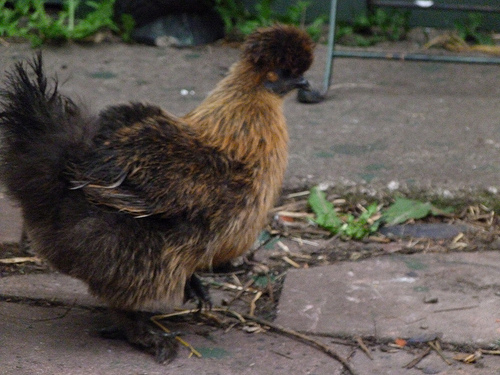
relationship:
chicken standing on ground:
[2, 23, 314, 333] [1, 35, 498, 374]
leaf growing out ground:
[309, 187, 381, 242] [1, 35, 498, 374]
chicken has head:
[2, 23, 314, 333] [239, 28, 311, 98]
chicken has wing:
[2, 23, 314, 333] [78, 117, 238, 218]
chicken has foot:
[2, 23, 314, 333] [102, 302, 180, 361]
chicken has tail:
[2, 23, 314, 333] [1, 53, 87, 237]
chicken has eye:
[2, 23, 314, 333] [280, 69, 291, 80]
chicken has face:
[2, 23, 314, 333] [275, 63, 309, 95]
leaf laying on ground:
[309, 187, 381, 242] [1, 35, 498, 374]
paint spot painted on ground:
[184, 341, 236, 359] [1, 35, 498, 374]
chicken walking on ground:
[2, 23, 314, 333] [1, 35, 498, 374]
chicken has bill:
[2, 23, 314, 333] [292, 78, 309, 90]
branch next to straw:
[233, 307, 353, 370] [153, 300, 254, 354]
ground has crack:
[1, 35, 498, 374] [3, 285, 498, 360]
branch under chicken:
[233, 307, 353, 370] [2, 23, 314, 333]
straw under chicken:
[153, 300, 254, 354] [2, 23, 314, 333]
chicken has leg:
[2, 23, 314, 333] [84, 236, 181, 361]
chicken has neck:
[2, 23, 314, 333] [188, 70, 295, 160]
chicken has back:
[2, 23, 314, 333] [74, 97, 202, 170]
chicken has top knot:
[2, 23, 314, 333] [253, 22, 313, 69]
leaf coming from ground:
[309, 187, 381, 242] [1, 35, 498, 374]